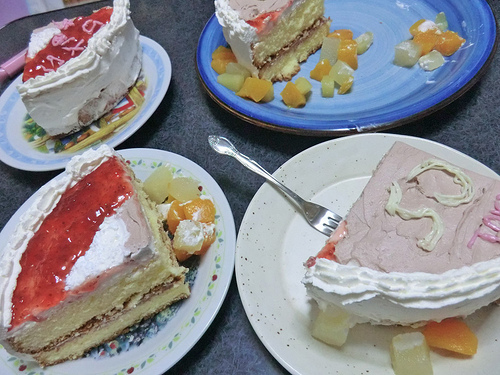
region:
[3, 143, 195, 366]
slice of cake with red fruit sauce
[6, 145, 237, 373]
round flowered ceramic plate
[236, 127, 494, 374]
round white ceramic plate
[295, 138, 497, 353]
slice of cake with pink icing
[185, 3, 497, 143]
round blue ceramic plate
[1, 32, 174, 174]
ceramic plate with blue border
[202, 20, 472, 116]
fruit pieces on blue plate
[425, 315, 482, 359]
piece of diced peach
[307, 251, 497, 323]
white icing on cake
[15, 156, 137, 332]
red berry sauce on cake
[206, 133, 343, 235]
the fork on the plate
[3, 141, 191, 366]
the desert on the plate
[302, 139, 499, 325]
the desert on the plate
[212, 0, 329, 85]
the desert on the plate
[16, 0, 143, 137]
the desert on the plate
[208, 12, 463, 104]
the fruit on the plate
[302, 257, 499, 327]
the white frosting on the cake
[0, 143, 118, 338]
the white frosting on the cake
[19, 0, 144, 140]
the white frosting on the cake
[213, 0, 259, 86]
the white frosting on the cake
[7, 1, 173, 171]
cake on top of plate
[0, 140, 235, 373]
large slice of cake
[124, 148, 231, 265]
fruit on side of plate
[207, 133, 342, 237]
silver fork on plate edge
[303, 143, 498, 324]
pink frosting on cake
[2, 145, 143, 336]
fruit sauce on cake top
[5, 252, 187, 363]
cake with two layers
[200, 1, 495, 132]
fruit on blue plate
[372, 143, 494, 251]
writing on cake frosting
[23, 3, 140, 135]
white frosting on cake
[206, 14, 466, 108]
chunks of fruit on the blue plate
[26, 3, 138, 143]
cake with white frosting around the side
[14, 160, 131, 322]
cake with strawberry glaze decorating the top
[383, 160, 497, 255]
pink and white writing on the cake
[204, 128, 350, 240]
fork on the white plate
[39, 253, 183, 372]
two-layered cake with filling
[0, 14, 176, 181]
small plate with light blue decorating the outer rim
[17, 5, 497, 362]
a cake has been cut into four large wedges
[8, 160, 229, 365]
cake served with a side of canned fruit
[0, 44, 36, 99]
a pink plastic object sits by a piece of cake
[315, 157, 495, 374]
cake on the plate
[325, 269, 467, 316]
white frosting on cake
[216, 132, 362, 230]
fork on the plate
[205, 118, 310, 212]
handle of the fork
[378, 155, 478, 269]
the number 50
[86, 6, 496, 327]
four plates of cake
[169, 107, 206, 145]
table under the plates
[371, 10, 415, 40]
blue plate in the photo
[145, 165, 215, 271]
many food items on plate